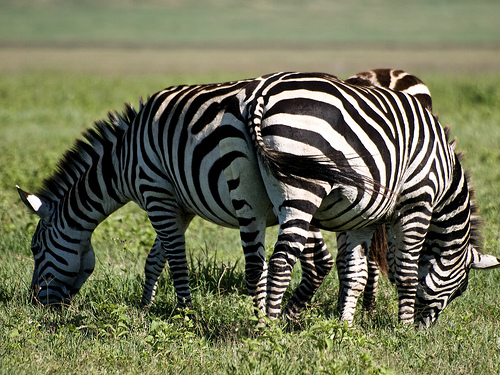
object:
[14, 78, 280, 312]
zebra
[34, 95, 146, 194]
mane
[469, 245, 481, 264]
stripes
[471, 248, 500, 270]
ear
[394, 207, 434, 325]
front legs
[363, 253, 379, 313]
front legs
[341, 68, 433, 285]
zebra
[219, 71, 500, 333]
zebra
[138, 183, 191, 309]
leg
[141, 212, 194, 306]
leg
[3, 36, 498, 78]
road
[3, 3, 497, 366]
grass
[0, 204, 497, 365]
forefront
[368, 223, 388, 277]
tail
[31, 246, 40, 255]
eye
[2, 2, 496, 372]
ground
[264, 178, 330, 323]
leg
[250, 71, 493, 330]
person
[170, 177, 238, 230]
zebra`s stomach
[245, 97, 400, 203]
tail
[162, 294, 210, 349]
weed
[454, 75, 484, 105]
bush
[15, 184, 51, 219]
ear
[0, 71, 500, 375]
foreground